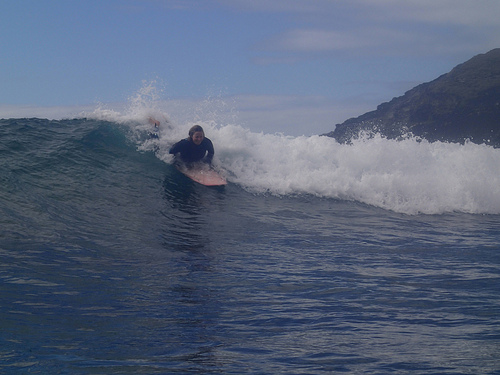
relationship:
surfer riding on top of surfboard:
[169, 124, 216, 168] [166, 160, 230, 191]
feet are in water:
[145, 114, 162, 128] [5, 118, 499, 374]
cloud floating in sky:
[285, 27, 374, 54] [1, 3, 499, 122]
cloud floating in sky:
[371, 2, 500, 24] [1, 3, 499, 122]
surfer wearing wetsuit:
[169, 124, 216, 168] [166, 140, 215, 164]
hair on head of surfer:
[190, 125, 205, 137] [169, 124, 216, 168]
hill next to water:
[313, 45, 498, 148] [5, 118, 499, 374]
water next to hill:
[5, 118, 499, 374] [313, 45, 498, 148]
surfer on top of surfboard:
[169, 124, 216, 168] [166, 160, 230, 191]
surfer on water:
[169, 124, 216, 168] [5, 118, 499, 374]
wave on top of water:
[114, 106, 498, 214] [5, 118, 499, 374]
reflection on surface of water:
[166, 169, 224, 322] [5, 118, 499, 374]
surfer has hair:
[169, 124, 216, 168] [190, 125, 205, 137]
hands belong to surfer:
[176, 160, 214, 173] [169, 124, 216, 168]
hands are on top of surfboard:
[176, 160, 214, 173] [166, 160, 230, 191]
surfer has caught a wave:
[169, 124, 216, 168] [114, 106, 498, 214]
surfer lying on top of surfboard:
[169, 124, 216, 168] [166, 160, 230, 191]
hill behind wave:
[313, 45, 498, 148] [114, 106, 498, 214]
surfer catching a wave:
[169, 124, 216, 168] [114, 106, 498, 214]